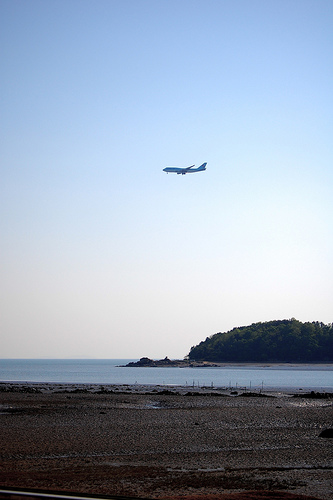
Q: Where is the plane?
A: The Sky.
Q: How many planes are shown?
A: One.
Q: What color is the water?
A: Blue.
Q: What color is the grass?
A: Green.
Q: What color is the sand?
A: Tan.